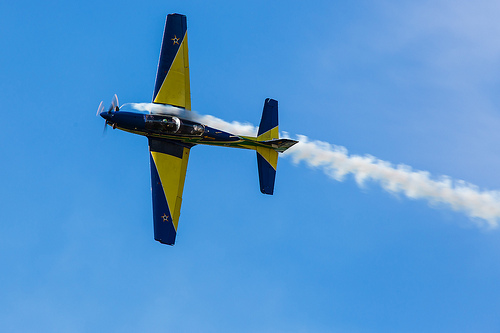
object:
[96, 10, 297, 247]
stunt plane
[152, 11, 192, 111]
wing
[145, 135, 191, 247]
wing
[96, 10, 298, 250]
jet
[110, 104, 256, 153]
engine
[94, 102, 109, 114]
helix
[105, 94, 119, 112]
helix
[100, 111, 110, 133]
helix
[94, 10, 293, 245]
plane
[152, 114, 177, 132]
seat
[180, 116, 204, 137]
seat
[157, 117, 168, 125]
pilot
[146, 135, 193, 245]
left wing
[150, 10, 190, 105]
right wing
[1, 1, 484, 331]
sky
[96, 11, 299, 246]
airplane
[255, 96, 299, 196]
tail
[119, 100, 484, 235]
smoke